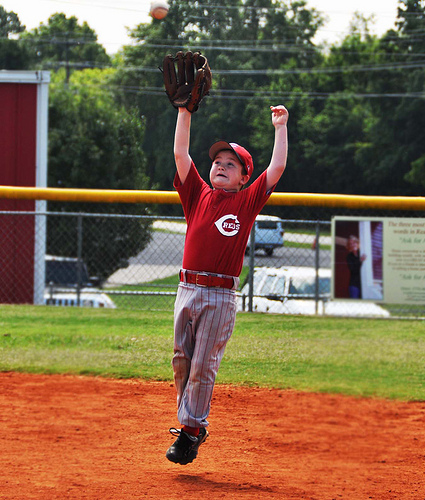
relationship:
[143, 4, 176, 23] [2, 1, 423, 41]
baseball in mid-air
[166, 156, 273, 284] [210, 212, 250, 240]
uniform for chicago reds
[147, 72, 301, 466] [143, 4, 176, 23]
boy playing baseball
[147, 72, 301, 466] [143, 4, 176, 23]
boy catching ball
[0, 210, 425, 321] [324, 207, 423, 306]
fence has a sign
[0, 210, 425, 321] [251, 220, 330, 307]
fence linked chain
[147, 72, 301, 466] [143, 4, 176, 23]
kid playing baseball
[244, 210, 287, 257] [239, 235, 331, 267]
car on road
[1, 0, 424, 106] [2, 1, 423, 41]
electric wires in sky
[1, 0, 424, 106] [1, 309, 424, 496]
trees outside baseball court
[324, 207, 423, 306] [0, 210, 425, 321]
advertisement on fence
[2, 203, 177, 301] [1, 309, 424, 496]
fence surround baseball court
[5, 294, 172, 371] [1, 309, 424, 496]
grass on baseball court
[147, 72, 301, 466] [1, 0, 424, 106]
boy jumping in air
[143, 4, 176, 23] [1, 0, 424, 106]
baseball in air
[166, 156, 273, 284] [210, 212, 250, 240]
shirt has logo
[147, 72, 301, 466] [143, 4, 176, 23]
boy about catch ball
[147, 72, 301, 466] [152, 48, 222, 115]
boy wearing mitt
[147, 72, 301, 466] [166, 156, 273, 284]
boy wearing red shirt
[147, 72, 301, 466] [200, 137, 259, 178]
boy wearing cap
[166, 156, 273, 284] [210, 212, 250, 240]
shirt has white logo